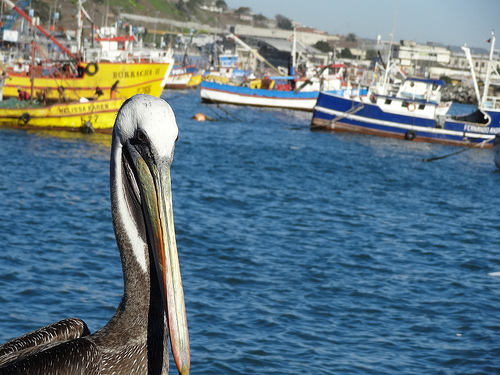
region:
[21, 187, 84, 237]
body of a water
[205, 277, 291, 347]
body of a water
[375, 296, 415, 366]
body of a water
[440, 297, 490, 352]
body of a water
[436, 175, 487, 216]
body of a water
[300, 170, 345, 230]
body of a water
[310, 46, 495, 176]
boat on a dock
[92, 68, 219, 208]
head of a bird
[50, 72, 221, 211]
head of the bird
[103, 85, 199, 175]
white head of bird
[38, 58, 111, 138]
yellow ships in water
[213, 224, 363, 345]
ripples in the water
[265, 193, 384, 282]
water behind the bird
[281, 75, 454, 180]
blue and white bird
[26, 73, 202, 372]
gray and white bird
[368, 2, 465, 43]
sky above the land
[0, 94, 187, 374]
bird near the camera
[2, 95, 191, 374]
bird is a pelican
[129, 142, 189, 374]
beak of the pelican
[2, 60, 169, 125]
the boats are yellow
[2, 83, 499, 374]
the sea is calm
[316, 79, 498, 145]
blue and whtie boat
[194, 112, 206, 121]
a buoy is floating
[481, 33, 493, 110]
the pole is white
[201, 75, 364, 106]
red white and blue boat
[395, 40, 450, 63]
building in the distance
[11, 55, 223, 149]
these boats are yellow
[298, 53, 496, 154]
the boat is blue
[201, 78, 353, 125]
this boat is blue & white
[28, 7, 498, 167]
many boats at anchor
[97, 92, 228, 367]
the pelican has a very long beak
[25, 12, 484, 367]
a beautiful coastal picture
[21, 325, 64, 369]
the bird has brown feathers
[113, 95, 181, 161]
the bird has a white head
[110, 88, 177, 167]
white head of a bird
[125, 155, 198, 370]
long beak of bird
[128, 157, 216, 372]
long yellow beak of pelican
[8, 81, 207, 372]
long neck of pelican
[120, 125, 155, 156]
black eye of bird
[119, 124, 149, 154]
black eye of pelican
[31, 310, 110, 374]
black wings on back of bird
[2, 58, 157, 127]
yellow paint on body of boat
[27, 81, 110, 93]
red line on boat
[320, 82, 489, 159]
blue boat in water